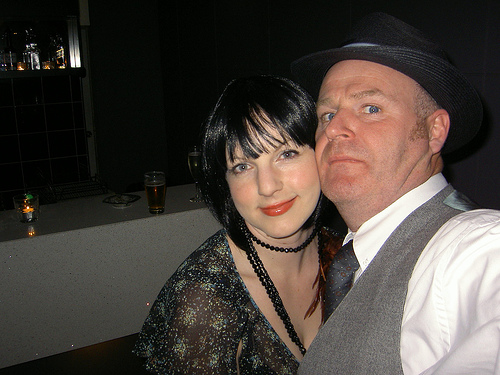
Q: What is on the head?
A: A hat.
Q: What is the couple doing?
A: Taking a picture.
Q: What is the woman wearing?
A: Lipstick.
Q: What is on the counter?
A: Drinnks.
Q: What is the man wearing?
A: Vest.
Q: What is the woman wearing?
A: Black top.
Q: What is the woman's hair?
A: Black.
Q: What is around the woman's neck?
A: A black necklace.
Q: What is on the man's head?
A: A black hat.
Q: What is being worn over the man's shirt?
A: A gray vest.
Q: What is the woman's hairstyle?
A: Black medium length with bangs.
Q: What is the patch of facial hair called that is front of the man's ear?
A: A side burn.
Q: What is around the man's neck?
A: A neck tie.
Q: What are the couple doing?
A: Posing.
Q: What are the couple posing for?
A: A picture.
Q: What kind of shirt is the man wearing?
A: A white dress shirt.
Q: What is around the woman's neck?
A: Beads.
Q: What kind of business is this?
A: Bar.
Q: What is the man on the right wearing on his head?
A: Hat.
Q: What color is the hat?
A: Black.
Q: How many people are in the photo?
A: Two.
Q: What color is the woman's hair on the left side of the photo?
A: Black.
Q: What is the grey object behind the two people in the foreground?
A: Countertop.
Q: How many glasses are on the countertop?
A: Three.